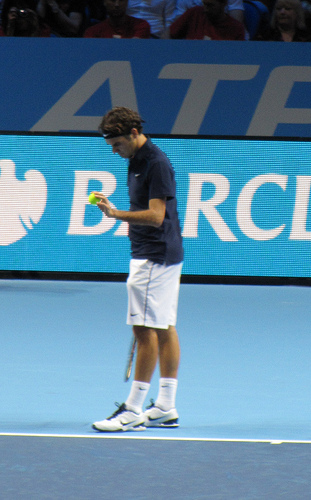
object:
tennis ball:
[87, 188, 103, 205]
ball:
[87, 191, 101, 204]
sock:
[154, 377, 177, 410]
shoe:
[91, 400, 145, 431]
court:
[0, 275, 310, 437]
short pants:
[122, 252, 181, 329]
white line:
[4, 427, 309, 447]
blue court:
[0, 277, 310, 499]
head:
[92, 105, 146, 164]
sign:
[0, 130, 310, 277]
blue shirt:
[117, 129, 184, 264]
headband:
[94, 122, 146, 137]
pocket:
[138, 254, 167, 272]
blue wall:
[0, 37, 310, 273]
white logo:
[0, 42, 309, 137]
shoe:
[144, 397, 179, 427]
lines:
[0, 420, 307, 459]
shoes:
[86, 403, 186, 430]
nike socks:
[124, 372, 177, 411]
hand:
[91, 190, 113, 217]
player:
[88, 108, 181, 435]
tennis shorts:
[124, 253, 183, 327]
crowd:
[1, 2, 310, 41]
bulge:
[122, 272, 141, 294]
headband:
[102, 127, 140, 136]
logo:
[0, 156, 310, 251]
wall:
[0, 133, 310, 280]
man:
[67, 107, 205, 440]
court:
[2, 279, 310, 498]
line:
[0, 431, 309, 445]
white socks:
[130, 382, 177, 400]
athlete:
[85, 98, 194, 433]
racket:
[124, 331, 139, 380]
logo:
[136, 382, 148, 392]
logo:
[158, 382, 168, 389]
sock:
[122, 380, 150, 414]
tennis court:
[6, 280, 310, 498]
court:
[1, 435, 311, 499]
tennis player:
[90, 104, 186, 431]